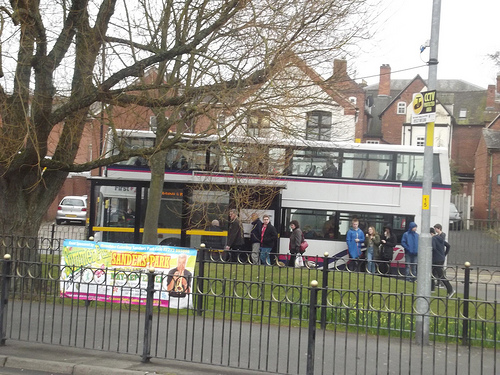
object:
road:
[40, 223, 498, 305]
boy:
[346, 218, 365, 273]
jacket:
[346, 225, 366, 258]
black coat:
[258, 221, 279, 248]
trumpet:
[175, 269, 185, 294]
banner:
[58, 239, 199, 310]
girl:
[364, 226, 380, 274]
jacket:
[365, 231, 380, 257]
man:
[430, 227, 457, 299]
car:
[56, 195, 88, 225]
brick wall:
[63, 177, 88, 189]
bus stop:
[89, 175, 283, 267]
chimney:
[377, 64, 391, 97]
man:
[225, 209, 246, 262]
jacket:
[226, 215, 245, 246]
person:
[288, 220, 308, 267]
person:
[345, 218, 364, 272]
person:
[400, 221, 420, 277]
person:
[258, 213, 278, 265]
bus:
[93, 127, 450, 273]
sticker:
[422, 195, 429, 210]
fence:
[258, 249, 500, 348]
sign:
[410, 88, 438, 126]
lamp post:
[414, 0, 444, 346]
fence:
[0, 254, 500, 375]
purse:
[300, 241, 309, 251]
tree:
[0, 0, 385, 293]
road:
[0, 289, 497, 375]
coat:
[289, 226, 306, 253]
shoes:
[445, 289, 458, 299]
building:
[46, 51, 500, 251]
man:
[166, 254, 193, 298]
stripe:
[92, 226, 229, 237]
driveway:
[37, 198, 90, 257]